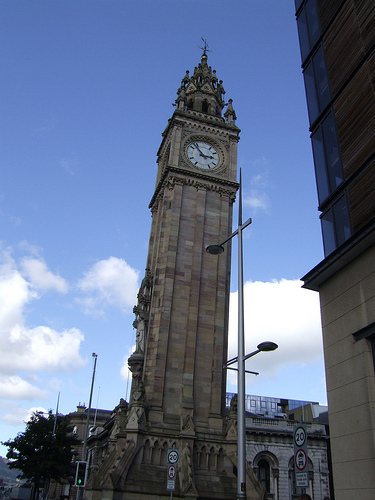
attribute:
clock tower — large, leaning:
[80, 35, 266, 497]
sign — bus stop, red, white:
[284, 437, 319, 468]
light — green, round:
[206, 242, 224, 253]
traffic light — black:
[70, 458, 91, 490]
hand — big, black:
[192, 139, 203, 154]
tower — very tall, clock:
[121, 35, 238, 410]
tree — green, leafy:
[0, 405, 80, 494]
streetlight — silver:
[185, 224, 299, 455]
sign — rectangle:
[292, 423, 307, 488]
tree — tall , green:
[6, 406, 92, 498]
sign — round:
[289, 424, 310, 449]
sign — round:
[166, 449, 183, 462]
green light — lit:
[75, 475, 83, 484]